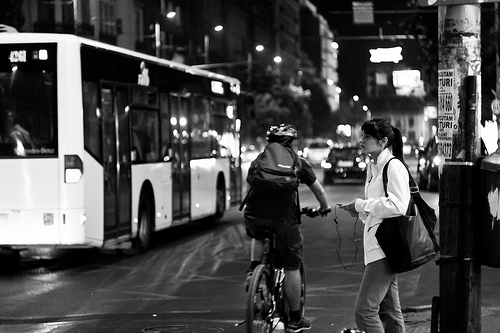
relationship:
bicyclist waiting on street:
[243, 122, 331, 329] [118, 259, 159, 309]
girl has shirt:
[338, 118, 414, 331] [352, 145, 412, 267]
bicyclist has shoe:
[243, 122, 331, 329] [283, 316, 313, 331]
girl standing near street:
[338, 118, 414, 331] [2, 149, 499, 331]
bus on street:
[1, 24, 242, 254] [0, 180, 498, 330]